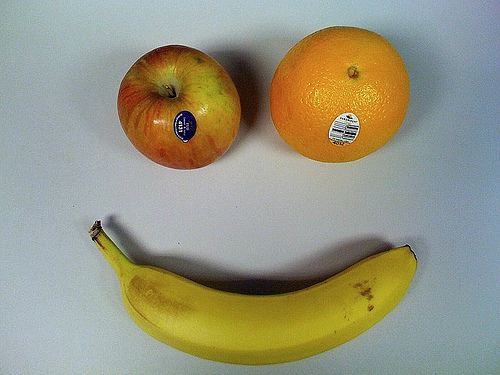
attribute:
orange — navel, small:
[274, 25, 408, 167]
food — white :
[80, 21, 429, 361]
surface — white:
[224, 184, 316, 256]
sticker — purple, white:
[170, 109, 198, 142]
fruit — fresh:
[103, 30, 423, 370]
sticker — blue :
[160, 112, 211, 145]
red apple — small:
[114, 40, 245, 172]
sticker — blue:
[171, 105, 198, 143]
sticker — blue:
[325, 112, 362, 154]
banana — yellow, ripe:
[73, 218, 417, 368]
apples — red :
[115, 44, 241, 171]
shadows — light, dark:
[194, 27, 257, 70]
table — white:
[98, 166, 460, 227]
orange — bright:
[268, 14, 428, 174]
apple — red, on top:
[114, 39, 242, 173]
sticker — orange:
[322, 108, 357, 148]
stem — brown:
[84, 210, 106, 240]